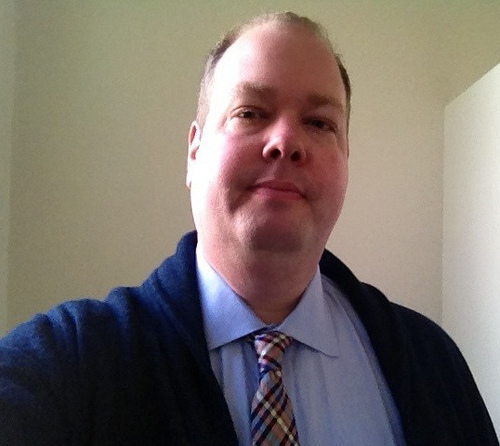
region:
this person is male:
[103, 26, 421, 391]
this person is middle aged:
[168, 77, 400, 304]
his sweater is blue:
[141, 219, 489, 411]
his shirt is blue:
[93, 220, 451, 420]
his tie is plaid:
[223, 308, 405, 433]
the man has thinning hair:
[103, 16, 396, 378]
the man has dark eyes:
[139, 34, 403, 346]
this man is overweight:
[122, 27, 419, 393]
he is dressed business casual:
[110, 22, 428, 409]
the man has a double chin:
[144, 22, 405, 359]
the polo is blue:
[290, 341, 450, 432]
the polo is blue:
[283, 341, 328, 389]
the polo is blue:
[311, 330, 348, 406]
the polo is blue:
[266, 328, 373, 439]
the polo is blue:
[283, 345, 341, 433]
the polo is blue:
[315, 320, 365, 432]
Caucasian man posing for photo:
[127, 12, 404, 438]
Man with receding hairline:
[197, 21, 366, 148]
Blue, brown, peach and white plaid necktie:
[234, 321, 310, 443]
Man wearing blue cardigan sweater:
[32, 236, 492, 443]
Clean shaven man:
[198, 35, 352, 266]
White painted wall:
[367, 63, 498, 293]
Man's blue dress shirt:
[147, 300, 393, 444]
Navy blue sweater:
[46, 264, 230, 439]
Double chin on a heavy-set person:
[197, 171, 344, 306]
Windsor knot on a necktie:
[187, 300, 341, 405]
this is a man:
[115, 29, 354, 444]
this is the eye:
[300, 113, 340, 135]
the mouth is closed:
[242, 175, 309, 200]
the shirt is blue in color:
[311, 346, 373, 416]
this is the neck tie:
[256, 336, 296, 441]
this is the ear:
[180, 122, 202, 185]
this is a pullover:
[68, 306, 188, 443]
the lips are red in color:
[251, 177, 301, 198]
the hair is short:
[207, 31, 233, 54]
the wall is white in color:
[0, 19, 146, 212]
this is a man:
[176, 39, 378, 400]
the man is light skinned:
[236, 225, 279, 255]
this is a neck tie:
[251, 355, 298, 445]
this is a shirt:
[308, 382, 350, 417]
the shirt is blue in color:
[308, 388, 339, 415]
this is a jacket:
[66, 315, 141, 383]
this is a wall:
[55, 56, 126, 173]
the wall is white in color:
[76, 42, 123, 157]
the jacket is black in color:
[93, 333, 143, 410]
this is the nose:
[263, 134, 303, 154]